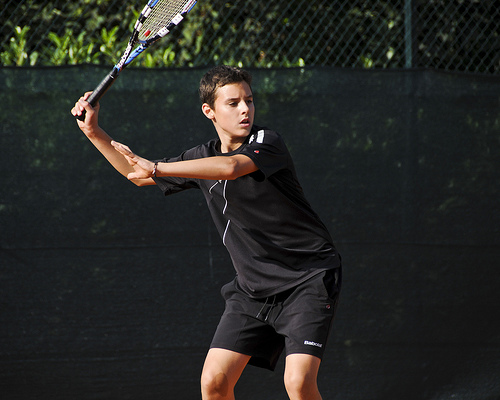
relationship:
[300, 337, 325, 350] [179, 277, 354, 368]
logo on shorts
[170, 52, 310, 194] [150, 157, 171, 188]
boy wearing a bracelet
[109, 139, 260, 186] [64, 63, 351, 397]
arm of a man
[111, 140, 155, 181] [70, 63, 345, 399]
hand of a boy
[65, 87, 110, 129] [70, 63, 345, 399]
hand of a boy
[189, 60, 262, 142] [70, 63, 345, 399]
head of a boy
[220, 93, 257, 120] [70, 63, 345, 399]
nose of a boy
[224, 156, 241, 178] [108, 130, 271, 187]
elbow of an arm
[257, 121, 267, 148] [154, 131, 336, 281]
stripe on shirt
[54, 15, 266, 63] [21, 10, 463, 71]
trees behind fence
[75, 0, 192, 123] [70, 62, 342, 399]
racket on boy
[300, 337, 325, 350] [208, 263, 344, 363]
logo on shorts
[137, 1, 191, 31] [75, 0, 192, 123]
strings on racket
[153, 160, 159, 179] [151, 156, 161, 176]
bracelet on boy's wrist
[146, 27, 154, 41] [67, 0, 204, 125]
sticker on racket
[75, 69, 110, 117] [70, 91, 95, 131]
handle on boy's hand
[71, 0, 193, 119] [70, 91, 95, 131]
racket in boy's hand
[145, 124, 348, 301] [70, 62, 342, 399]
shirt on boy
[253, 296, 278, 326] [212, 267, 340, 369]
string on shorts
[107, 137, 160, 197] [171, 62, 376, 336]
hand on boy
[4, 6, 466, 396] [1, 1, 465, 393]
fence around tennis court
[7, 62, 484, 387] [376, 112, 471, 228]
fabric on fence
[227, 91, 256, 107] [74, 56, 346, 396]
eye on person